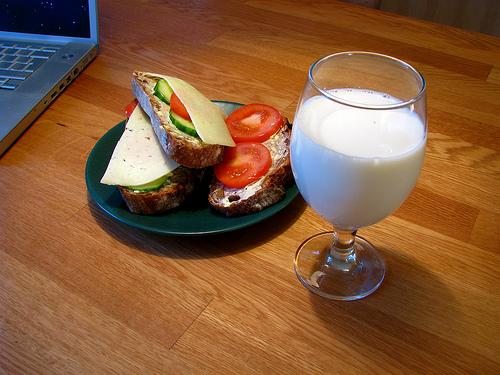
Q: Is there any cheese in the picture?
A: Yes, there is cheese.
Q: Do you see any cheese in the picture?
A: Yes, there is cheese.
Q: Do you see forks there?
A: No, there are no forks.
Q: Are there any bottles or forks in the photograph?
A: No, there are no forks or bottles.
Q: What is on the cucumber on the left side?
A: The cheese is on the cucumber.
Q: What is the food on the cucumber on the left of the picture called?
A: The food is cheese.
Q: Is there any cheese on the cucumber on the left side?
A: Yes, there is cheese on the cucumber.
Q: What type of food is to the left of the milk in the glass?
A: The food is cheese.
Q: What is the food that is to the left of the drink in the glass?
A: The food is cheese.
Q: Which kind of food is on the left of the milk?
A: The food is cheese.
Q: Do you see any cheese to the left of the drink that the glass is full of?
A: Yes, there is cheese to the left of the milk.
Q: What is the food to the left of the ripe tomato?
A: The food is cheese.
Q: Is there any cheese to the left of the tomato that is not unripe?
A: Yes, there is cheese to the left of the tomato.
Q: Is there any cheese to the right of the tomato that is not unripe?
A: No, the cheese is to the left of the tomato.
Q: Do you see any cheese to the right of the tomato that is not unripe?
A: No, the cheese is to the left of the tomato.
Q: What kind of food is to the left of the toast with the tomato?
A: The food is cheese.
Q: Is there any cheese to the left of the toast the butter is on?
A: Yes, there is cheese to the left of the toast.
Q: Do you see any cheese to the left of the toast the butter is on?
A: Yes, there is cheese to the left of the toast.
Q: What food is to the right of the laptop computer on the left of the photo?
A: The food is cheese.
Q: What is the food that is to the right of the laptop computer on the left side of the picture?
A: The food is cheese.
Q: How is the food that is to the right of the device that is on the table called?
A: The food is cheese.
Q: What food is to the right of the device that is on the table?
A: The food is cheese.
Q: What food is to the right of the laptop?
A: The food is cheese.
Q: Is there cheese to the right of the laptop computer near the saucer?
A: Yes, there is cheese to the right of the laptop.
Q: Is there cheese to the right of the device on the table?
A: Yes, there is cheese to the right of the laptop.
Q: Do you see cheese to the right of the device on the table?
A: Yes, there is cheese to the right of the laptop.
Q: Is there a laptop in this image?
A: Yes, there is a laptop.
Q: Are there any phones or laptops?
A: Yes, there is a laptop.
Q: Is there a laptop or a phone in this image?
A: Yes, there is a laptop.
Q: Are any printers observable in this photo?
A: No, there are no printers.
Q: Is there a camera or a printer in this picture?
A: No, there are no printers or cameras.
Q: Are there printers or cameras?
A: No, there are no printers or cameras.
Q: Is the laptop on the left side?
A: Yes, the laptop is on the left of the image.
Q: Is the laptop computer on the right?
A: No, the laptop computer is on the left of the image.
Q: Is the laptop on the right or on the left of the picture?
A: The laptop is on the left of the image.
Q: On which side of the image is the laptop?
A: The laptop is on the left of the image.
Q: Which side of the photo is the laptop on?
A: The laptop is on the left of the image.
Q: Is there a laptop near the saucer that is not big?
A: Yes, there is a laptop near the saucer.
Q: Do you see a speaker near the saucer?
A: No, there is a laptop near the saucer.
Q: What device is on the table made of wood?
A: The device is a laptop.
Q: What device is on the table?
A: The device is a laptop.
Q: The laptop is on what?
A: The laptop is on the table.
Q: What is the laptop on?
A: The laptop is on the table.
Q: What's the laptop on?
A: The laptop is on the table.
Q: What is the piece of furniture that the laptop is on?
A: The piece of furniture is a table.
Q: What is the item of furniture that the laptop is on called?
A: The piece of furniture is a table.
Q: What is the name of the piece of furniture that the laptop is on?
A: The piece of furniture is a table.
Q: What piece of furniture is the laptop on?
A: The laptop is on the table.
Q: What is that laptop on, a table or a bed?
A: The laptop is on a table.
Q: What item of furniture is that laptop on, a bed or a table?
A: The laptop is on a table.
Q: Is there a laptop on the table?
A: Yes, there is a laptop on the table.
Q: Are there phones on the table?
A: No, there is a laptop on the table.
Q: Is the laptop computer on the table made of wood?
A: Yes, the laptop computer is on the table.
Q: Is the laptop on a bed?
A: No, the laptop is on the table.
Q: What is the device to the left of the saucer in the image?
A: The device is a laptop.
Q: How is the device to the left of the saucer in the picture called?
A: The device is a laptop.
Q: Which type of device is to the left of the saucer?
A: The device is a laptop.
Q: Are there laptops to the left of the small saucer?
A: Yes, there is a laptop to the left of the saucer.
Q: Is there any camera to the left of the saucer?
A: No, there is a laptop to the left of the saucer.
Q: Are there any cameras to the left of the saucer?
A: No, there is a laptop to the left of the saucer.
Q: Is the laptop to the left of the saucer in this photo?
A: Yes, the laptop is to the left of the saucer.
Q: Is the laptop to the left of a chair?
A: No, the laptop is to the left of the saucer.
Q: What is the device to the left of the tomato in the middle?
A: The device is a laptop.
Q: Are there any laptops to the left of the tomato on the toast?
A: Yes, there is a laptop to the left of the tomato.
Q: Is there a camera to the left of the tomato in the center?
A: No, there is a laptop to the left of the tomato.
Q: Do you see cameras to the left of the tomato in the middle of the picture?
A: No, there is a laptop to the left of the tomato.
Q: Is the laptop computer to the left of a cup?
A: No, the laptop computer is to the left of the tomato.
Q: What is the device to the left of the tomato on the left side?
A: The device is a laptop.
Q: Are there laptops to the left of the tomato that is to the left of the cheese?
A: Yes, there is a laptop to the left of the tomato.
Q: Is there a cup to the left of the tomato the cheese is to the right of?
A: No, there is a laptop to the left of the tomato.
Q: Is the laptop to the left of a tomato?
A: Yes, the laptop is to the left of a tomato.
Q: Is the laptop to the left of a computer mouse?
A: No, the laptop is to the left of a tomato.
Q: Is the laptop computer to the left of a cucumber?
A: Yes, the laptop computer is to the left of a cucumber.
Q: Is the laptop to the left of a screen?
A: No, the laptop is to the left of a cucumber.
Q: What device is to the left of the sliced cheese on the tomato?
A: The device is a laptop.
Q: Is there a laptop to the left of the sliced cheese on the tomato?
A: Yes, there is a laptop to the left of the cheese.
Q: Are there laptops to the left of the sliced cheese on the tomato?
A: Yes, there is a laptop to the left of the cheese.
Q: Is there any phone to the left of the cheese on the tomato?
A: No, there is a laptop to the left of the cheese.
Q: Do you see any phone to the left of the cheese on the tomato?
A: No, there is a laptop to the left of the cheese.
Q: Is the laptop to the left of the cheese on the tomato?
A: Yes, the laptop is to the left of the cheese.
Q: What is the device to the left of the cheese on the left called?
A: The device is a laptop.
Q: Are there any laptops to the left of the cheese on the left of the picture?
A: Yes, there is a laptop to the left of the cheese.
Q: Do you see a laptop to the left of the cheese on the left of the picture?
A: Yes, there is a laptop to the left of the cheese.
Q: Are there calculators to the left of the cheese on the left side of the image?
A: No, there is a laptop to the left of the cheese.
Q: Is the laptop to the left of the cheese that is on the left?
A: Yes, the laptop is to the left of the cheese.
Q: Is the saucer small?
A: Yes, the saucer is small.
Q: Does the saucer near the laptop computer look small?
A: Yes, the saucer is small.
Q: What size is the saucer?
A: The saucer is small.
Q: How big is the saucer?
A: The saucer is small.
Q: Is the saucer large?
A: No, the saucer is small.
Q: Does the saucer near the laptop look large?
A: No, the saucer is small.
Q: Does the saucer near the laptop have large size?
A: No, the saucer is small.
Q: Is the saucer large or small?
A: The saucer is small.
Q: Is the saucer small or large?
A: The saucer is small.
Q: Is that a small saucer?
A: Yes, that is a small saucer.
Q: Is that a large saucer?
A: No, that is a small saucer.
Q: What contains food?
A: The saucer contains food.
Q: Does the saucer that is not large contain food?
A: Yes, the saucer contains food.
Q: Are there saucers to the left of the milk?
A: Yes, there is a saucer to the left of the milk.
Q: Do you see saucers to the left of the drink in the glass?
A: Yes, there is a saucer to the left of the milk.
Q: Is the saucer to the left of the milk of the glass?
A: Yes, the saucer is to the left of the milk.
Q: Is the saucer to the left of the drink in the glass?
A: Yes, the saucer is to the left of the milk.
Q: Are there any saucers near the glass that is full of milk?
A: Yes, there is a saucer near the glass.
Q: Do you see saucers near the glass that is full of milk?
A: Yes, there is a saucer near the glass.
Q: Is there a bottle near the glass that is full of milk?
A: No, there is a saucer near the glass.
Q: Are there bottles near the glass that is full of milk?
A: No, there is a saucer near the glass.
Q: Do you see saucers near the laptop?
A: Yes, there is a saucer near the laptop.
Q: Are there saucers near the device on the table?
A: Yes, there is a saucer near the laptop.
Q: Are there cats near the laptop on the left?
A: No, there is a saucer near the laptop.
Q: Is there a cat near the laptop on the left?
A: No, there is a saucer near the laptop.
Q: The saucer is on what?
A: The saucer is on the table.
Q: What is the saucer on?
A: The saucer is on the table.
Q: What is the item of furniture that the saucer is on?
A: The piece of furniture is a table.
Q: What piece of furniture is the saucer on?
A: The saucer is on the table.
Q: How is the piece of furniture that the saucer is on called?
A: The piece of furniture is a table.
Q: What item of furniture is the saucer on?
A: The saucer is on the table.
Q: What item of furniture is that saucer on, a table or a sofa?
A: The saucer is on a table.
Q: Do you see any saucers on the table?
A: Yes, there is a saucer on the table.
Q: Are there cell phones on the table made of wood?
A: No, there is a saucer on the table.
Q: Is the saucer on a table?
A: Yes, the saucer is on a table.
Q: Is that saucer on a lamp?
A: No, the saucer is on a table.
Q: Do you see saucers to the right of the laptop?
A: Yes, there is a saucer to the right of the laptop.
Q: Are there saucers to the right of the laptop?
A: Yes, there is a saucer to the right of the laptop.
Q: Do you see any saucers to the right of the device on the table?
A: Yes, there is a saucer to the right of the laptop.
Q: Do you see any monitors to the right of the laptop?
A: No, there is a saucer to the right of the laptop.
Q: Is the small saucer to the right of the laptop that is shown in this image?
A: Yes, the saucer is to the right of the laptop.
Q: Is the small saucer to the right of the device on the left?
A: Yes, the saucer is to the right of the laptop.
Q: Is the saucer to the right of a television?
A: No, the saucer is to the right of the laptop.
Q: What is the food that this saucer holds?
A: The food is a toast.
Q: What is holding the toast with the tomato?
A: The saucer is holding the toast.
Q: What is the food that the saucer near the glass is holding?
A: The food is a toast.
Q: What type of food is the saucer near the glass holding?
A: The saucer is holding the toast.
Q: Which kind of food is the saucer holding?
A: The saucer is holding the toast.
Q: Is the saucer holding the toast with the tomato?
A: Yes, the saucer is holding the toast.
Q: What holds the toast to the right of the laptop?
A: The saucer holds the toast.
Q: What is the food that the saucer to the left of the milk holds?
A: The food is a toast.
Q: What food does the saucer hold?
A: The saucer holds the toast.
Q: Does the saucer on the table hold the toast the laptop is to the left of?
A: Yes, the saucer holds the toast.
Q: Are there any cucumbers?
A: Yes, there is a cucumber.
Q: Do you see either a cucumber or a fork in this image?
A: Yes, there is a cucumber.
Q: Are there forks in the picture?
A: No, there are no forks.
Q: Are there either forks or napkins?
A: No, there are no forks or napkins.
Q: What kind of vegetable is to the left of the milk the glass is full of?
A: The vegetable is a cucumber.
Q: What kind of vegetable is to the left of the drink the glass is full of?
A: The vegetable is a cucumber.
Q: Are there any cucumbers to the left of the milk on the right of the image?
A: Yes, there is a cucumber to the left of the milk.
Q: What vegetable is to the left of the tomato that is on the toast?
A: The vegetable is a cucumber.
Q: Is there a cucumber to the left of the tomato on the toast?
A: Yes, there is a cucumber to the left of the tomato.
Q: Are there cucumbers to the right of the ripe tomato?
A: No, the cucumber is to the left of the tomato.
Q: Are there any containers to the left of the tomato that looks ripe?
A: No, there is a cucumber to the left of the tomato.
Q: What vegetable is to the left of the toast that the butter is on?
A: The vegetable is a cucumber.